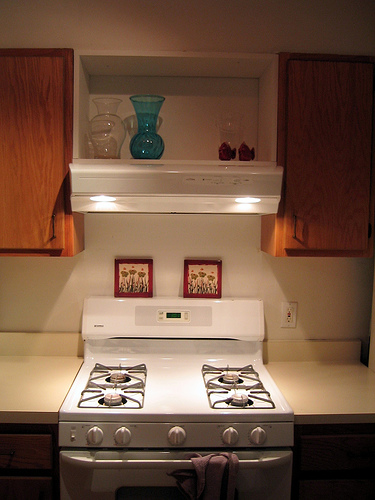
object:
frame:
[183, 256, 223, 299]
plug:
[287, 317, 291, 323]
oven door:
[57, 448, 295, 496]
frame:
[113, 258, 154, 298]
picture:
[118, 263, 149, 294]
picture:
[187, 263, 219, 294]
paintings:
[183, 259, 189, 298]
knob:
[87, 425, 105, 446]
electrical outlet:
[280, 301, 298, 328]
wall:
[0, 0, 373, 340]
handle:
[52, 214, 57, 238]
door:
[1, 51, 65, 250]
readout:
[166, 313, 182, 319]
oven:
[56, 294, 294, 498]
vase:
[86, 96, 127, 160]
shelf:
[65, 157, 284, 217]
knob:
[113, 425, 132, 446]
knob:
[167, 426, 187, 447]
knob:
[222, 426, 240, 446]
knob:
[249, 426, 267, 445]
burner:
[200, 364, 263, 389]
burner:
[205, 381, 276, 411]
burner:
[86, 362, 148, 387]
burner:
[77, 384, 146, 410]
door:
[58, 448, 296, 498]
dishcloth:
[190, 449, 241, 499]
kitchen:
[1, 1, 373, 498]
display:
[156, 308, 192, 324]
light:
[89, 195, 117, 202]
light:
[235, 197, 261, 205]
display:
[166, 313, 181, 319]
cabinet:
[258, 51, 373, 260]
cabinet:
[0, 43, 87, 261]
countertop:
[0, 328, 374, 415]